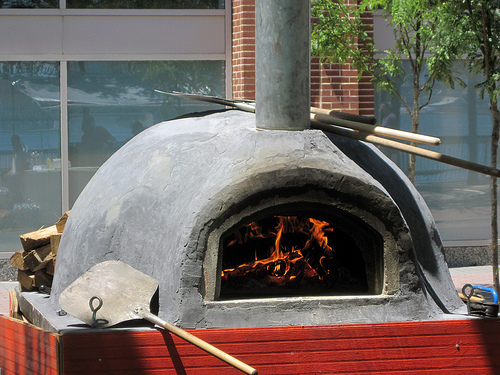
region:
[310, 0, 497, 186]
a tall green tree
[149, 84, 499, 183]
a long wooden stick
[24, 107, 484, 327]
a gray outdoor oven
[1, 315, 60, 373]
red brick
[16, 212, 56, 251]
a piece of firewood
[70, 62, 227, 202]
a window of a building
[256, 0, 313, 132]
a gray handle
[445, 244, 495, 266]
a small piece of concrete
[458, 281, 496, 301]
a blue iron handle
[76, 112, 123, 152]
a reflection of a person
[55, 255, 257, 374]
wooden pizza oven spatula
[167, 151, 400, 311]
wood fire oven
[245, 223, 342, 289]
pieces of wood on fire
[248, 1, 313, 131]
wide metal pipe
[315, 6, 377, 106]
green leaves with brick in background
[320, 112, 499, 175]
two light colored wooden poles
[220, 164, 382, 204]
blackened top of pizza oven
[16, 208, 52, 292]
several pieces of stacked wood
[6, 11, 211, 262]
two reflective glass windows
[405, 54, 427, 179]
thin light brown tree trunk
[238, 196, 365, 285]
fire in an oven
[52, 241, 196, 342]
big spatula next to oven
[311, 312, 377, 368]
red bottom of the oven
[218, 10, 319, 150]
silver pole above the oven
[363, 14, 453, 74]
leaves on a tree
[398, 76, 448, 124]
branches on the tree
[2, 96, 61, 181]
reflection in the window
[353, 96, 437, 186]
poles on top of the oven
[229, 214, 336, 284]
orange flames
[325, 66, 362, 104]
brick wall in the background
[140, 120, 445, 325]
The oven has a fire in it.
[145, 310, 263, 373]
The handle is made out of wood.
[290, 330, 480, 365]
Red bricks at the base of the oven.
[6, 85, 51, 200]
A window on the building.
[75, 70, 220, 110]
Another window on the building.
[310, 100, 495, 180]
The wood handles of tools.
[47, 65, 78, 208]
A bar is separating the two windows.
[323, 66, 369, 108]
Red bricks on the building.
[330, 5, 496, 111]
A green tree in the background.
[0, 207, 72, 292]
Wooden logs for the fire.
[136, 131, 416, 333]
brick oven with fire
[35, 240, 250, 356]
shovel for the brick oven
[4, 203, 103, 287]
stack of wood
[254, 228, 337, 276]
orange flames in dark hole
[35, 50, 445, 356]
large hot cement dome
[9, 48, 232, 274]
large square windows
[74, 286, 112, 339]
a hook on the brick oven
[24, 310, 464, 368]
dark red striped platform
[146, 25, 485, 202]
tool for the brick oven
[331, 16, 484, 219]
small tree with thin branches